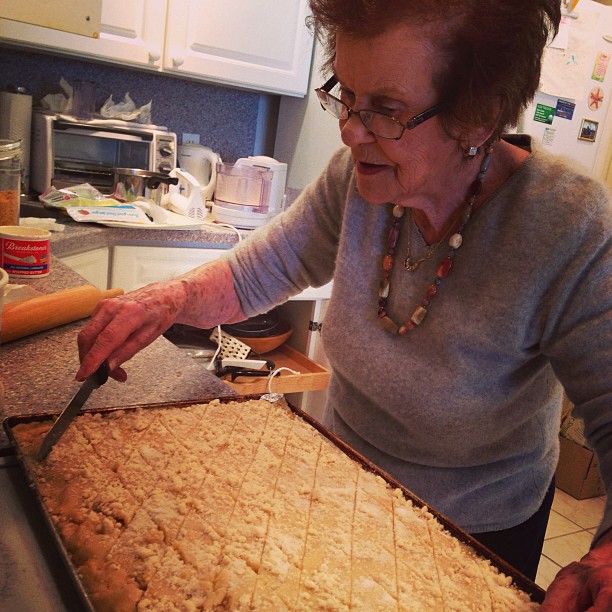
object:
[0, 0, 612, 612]
kitchen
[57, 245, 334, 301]
counter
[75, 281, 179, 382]
hand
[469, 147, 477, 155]
earring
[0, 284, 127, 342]
brown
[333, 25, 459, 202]
face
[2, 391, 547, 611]
pan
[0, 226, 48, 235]
icing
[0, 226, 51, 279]
containerr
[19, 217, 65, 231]
paper towels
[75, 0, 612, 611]
woman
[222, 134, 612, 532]
shirt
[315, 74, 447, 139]
eyeglasses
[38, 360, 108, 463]
knife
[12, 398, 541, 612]
baked goods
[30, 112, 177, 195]
microwave oven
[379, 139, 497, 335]
large beads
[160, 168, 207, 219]
mixer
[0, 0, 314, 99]
closed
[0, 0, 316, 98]
doors